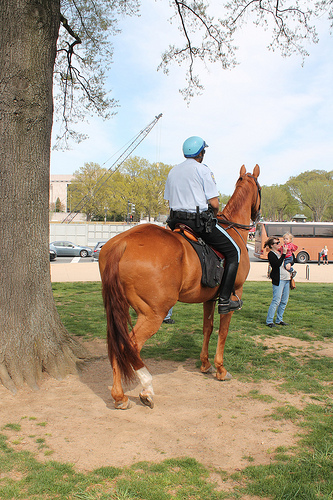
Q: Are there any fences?
A: No, there are no fences.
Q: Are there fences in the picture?
A: No, there are no fences.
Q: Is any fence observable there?
A: No, there are no fences.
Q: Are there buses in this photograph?
A: Yes, there is a bus.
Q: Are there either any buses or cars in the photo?
A: Yes, there is a bus.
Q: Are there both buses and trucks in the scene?
A: No, there is a bus but no trucks.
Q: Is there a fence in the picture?
A: No, there are no fences.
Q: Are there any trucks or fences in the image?
A: No, there are no fences or trucks.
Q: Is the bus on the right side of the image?
A: Yes, the bus is on the right of the image.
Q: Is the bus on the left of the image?
A: No, the bus is on the right of the image.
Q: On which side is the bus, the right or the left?
A: The bus is on the right of the image.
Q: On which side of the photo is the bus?
A: The bus is on the right of the image.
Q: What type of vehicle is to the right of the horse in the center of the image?
A: The vehicle is a bus.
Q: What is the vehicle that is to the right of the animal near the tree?
A: The vehicle is a bus.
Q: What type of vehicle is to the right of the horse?
A: The vehicle is a bus.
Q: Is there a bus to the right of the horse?
A: Yes, there is a bus to the right of the horse.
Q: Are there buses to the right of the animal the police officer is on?
A: Yes, there is a bus to the right of the horse.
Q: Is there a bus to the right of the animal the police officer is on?
A: Yes, there is a bus to the right of the horse.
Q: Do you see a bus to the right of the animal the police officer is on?
A: Yes, there is a bus to the right of the horse.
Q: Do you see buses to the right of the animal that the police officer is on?
A: Yes, there is a bus to the right of the horse.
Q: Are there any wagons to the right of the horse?
A: No, there is a bus to the right of the horse.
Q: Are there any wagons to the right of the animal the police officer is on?
A: No, there is a bus to the right of the horse.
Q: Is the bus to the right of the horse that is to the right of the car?
A: Yes, the bus is to the right of the horse.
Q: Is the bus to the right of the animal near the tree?
A: Yes, the bus is to the right of the horse.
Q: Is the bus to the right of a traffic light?
A: No, the bus is to the right of the horse.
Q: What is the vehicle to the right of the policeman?
A: The vehicle is a bus.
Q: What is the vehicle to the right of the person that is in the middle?
A: The vehicle is a bus.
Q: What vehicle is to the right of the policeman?
A: The vehicle is a bus.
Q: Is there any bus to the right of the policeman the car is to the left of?
A: Yes, there is a bus to the right of the police officer.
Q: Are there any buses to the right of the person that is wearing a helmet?
A: Yes, there is a bus to the right of the police officer.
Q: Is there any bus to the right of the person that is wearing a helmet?
A: Yes, there is a bus to the right of the police officer.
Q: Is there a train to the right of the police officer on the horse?
A: No, there is a bus to the right of the policeman.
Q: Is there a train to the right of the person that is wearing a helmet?
A: No, there is a bus to the right of the policeman.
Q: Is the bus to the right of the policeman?
A: Yes, the bus is to the right of the policeman.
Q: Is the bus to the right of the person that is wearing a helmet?
A: Yes, the bus is to the right of the policeman.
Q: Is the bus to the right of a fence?
A: No, the bus is to the right of the policeman.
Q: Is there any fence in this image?
A: No, there are no fences.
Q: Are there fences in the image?
A: No, there are no fences.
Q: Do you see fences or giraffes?
A: No, there are no fences or giraffes.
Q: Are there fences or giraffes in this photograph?
A: No, there are no fences or giraffes.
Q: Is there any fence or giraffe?
A: No, there are no fences or giraffes.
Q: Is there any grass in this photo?
A: Yes, there is grass.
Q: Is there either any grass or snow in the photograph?
A: Yes, there is grass.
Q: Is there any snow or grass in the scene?
A: Yes, there is grass.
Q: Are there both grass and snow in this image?
A: No, there is grass but no snow.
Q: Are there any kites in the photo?
A: No, there are no kites.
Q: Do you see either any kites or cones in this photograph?
A: No, there are no kites or cones.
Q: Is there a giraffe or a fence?
A: No, there are no fences or giraffes.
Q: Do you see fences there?
A: No, there are no fences.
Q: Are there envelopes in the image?
A: No, there are no envelopes.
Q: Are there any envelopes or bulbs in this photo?
A: No, there are no envelopes or bulbs.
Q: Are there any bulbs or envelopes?
A: No, there are no envelopes or bulbs.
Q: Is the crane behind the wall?
A: Yes, the crane is behind the wall.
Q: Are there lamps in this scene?
A: No, there are no lamps.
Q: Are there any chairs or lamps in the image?
A: No, there are no lamps or chairs.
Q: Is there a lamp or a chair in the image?
A: No, there are no lamps or chairs.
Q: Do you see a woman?
A: Yes, there is a woman.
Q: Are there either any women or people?
A: Yes, there is a woman.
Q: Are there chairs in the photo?
A: No, there are no chairs.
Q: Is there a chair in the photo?
A: No, there are no chairs.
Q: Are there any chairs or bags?
A: No, there are no chairs or bags.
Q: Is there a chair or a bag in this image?
A: No, there are no chairs or bags.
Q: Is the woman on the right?
A: Yes, the woman is on the right of the image.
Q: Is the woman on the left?
A: No, the woman is on the right of the image.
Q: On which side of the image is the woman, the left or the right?
A: The woman is on the right of the image.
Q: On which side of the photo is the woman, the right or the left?
A: The woman is on the right of the image.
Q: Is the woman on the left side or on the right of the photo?
A: The woman is on the right of the image.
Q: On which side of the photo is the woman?
A: The woman is on the right of the image.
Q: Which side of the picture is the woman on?
A: The woman is on the right of the image.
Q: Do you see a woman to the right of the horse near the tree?
A: Yes, there is a woman to the right of the horse.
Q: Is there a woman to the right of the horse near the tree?
A: Yes, there is a woman to the right of the horse.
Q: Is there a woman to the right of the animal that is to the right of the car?
A: Yes, there is a woman to the right of the horse.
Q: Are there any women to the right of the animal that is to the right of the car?
A: Yes, there is a woman to the right of the horse.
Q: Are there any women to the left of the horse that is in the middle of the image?
A: No, the woman is to the right of the horse.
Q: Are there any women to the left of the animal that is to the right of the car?
A: No, the woman is to the right of the horse.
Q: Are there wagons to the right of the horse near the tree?
A: No, there is a woman to the right of the horse.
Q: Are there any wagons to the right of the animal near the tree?
A: No, there is a woman to the right of the horse.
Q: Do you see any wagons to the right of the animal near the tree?
A: No, there is a woman to the right of the horse.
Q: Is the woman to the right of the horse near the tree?
A: Yes, the woman is to the right of the horse.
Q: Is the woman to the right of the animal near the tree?
A: Yes, the woman is to the right of the horse.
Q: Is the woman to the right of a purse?
A: No, the woman is to the right of the horse.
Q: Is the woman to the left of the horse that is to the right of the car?
A: No, the woman is to the right of the horse.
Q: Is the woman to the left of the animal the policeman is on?
A: No, the woman is to the right of the horse.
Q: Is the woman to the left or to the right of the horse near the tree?
A: The woman is to the right of the horse.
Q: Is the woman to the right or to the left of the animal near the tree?
A: The woman is to the right of the horse.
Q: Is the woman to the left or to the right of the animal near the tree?
A: The woman is to the right of the horse.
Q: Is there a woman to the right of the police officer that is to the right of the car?
A: Yes, there is a woman to the right of the police officer.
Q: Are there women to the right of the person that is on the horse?
A: Yes, there is a woman to the right of the police officer.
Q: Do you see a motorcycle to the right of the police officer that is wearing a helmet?
A: No, there is a woman to the right of the policeman.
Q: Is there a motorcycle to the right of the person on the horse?
A: No, there is a woman to the right of the policeman.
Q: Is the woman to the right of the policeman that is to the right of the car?
A: Yes, the woman is to the right of the police officer.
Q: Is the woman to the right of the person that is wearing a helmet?
A: Yes, the woman is to the right of the police officer.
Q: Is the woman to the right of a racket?
A: No, the woman is to the right of the police officer.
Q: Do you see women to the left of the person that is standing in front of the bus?
A: Yes, there is a woman to the left of the person.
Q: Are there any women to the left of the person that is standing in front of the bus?
A: Yes, there is a woman to the left of the person.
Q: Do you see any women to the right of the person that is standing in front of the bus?
A: No, the woman is to the left of the person.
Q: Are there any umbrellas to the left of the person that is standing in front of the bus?
A: No, there is a woman to the left of the person.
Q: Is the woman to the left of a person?
A: Yes, the woman is to the left of a person.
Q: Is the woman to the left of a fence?
A: No, the woman is to the left of a person.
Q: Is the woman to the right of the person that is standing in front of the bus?
A: No, the woman is to the left of the person.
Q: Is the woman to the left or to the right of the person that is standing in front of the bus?
A: The woman is to the left of the person.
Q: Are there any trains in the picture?
A: No, there are no trains.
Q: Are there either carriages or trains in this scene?
A: No, there are no trains or carriages.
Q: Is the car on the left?
A: Yes, the car is on the left of the image.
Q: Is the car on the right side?
A: No, the car is on the left of the image.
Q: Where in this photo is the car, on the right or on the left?
A: The car is on the left of the image.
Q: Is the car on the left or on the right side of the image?
A: The car is on the left of the image.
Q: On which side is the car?
A: The car is on the left of the image.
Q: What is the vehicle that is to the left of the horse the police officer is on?
A: The vehicle is a car.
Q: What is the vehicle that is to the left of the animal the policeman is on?
A: The vehicle is a car.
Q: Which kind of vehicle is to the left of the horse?
A: The vehicle is a car.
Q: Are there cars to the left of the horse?
A: Yes, there is a car to the left of the horse.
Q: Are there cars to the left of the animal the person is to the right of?
A: Yes, there is a car to the left of the horse.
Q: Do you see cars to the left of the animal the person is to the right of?
A: Yes, there is a car to the left of the horse.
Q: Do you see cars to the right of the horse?
A: No, the car is to the left of the horse.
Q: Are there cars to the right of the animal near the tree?
A: No, the car is to the left of the horse.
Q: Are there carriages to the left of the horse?
A: No, there is a car to the left of the horse.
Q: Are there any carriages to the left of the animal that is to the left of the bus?
A: No, there is a car to the left of the horse.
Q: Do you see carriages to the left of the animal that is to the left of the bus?
A: No, there is a car to the left of the horse.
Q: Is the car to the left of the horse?
A: Yes, the car is to the left of the horse.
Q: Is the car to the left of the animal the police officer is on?
A: Yes, the car is to the left of the horse.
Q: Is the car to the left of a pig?
A: No, the car is to the left of the horse.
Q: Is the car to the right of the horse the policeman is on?
A: No, the car is to the left of the horse.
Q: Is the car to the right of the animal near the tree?
A: No, the car is to the left of the horse.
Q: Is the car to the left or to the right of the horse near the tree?
A: The car is to the left of the horse.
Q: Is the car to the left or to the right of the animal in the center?
A: The car is to the left of the horse.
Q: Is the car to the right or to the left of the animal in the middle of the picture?
A: The car is to the left of the horse.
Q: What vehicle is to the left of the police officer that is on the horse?
A: The vehicle is a car.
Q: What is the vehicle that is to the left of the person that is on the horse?
A: The vehicle is a car.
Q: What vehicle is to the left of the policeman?
A: The vehicle is a car.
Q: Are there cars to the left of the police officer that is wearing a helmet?
A: Yes, there is a car to the left of the policeman.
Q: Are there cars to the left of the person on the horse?
A: Yes, there is a car to the left of the policeman.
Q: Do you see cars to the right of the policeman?
A: No, the car is to the left of the policeman.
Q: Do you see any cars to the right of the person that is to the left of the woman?
A: No, the car is to the left of the policeman.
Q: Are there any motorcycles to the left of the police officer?
A: No, there is a car to the left of the police officer.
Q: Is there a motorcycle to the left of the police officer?
A: No, there is a car to the left of the police officer.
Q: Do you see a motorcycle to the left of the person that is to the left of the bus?
A: No, there is a car to the left of the police officer.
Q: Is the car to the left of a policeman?
A: Yes, the car is to the left of a policeman.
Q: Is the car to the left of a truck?
A: No, the car is to the left of a policeman.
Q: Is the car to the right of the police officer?
A: No, the car is to the left of the police officer.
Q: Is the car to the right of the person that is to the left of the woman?
A: No, the car is to the left of the police officer.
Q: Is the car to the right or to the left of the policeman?
A: The car is to the left of the policeman.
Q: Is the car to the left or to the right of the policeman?
A: The car is to the left of the policeman.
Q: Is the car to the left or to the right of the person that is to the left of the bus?
A: The car is to the left of the policeman.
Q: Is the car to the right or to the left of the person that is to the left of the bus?
A: The car is to the left of the policeman.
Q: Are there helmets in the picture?
A: Yes, there is a helmet.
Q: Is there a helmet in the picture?
A: Yes, there is a helmet.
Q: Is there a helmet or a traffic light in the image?
A: Yes, there is a helmet.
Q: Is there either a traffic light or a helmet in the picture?
A: Yes, there is a helmet.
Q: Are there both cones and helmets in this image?
A: No, there is a helmet but no cones.